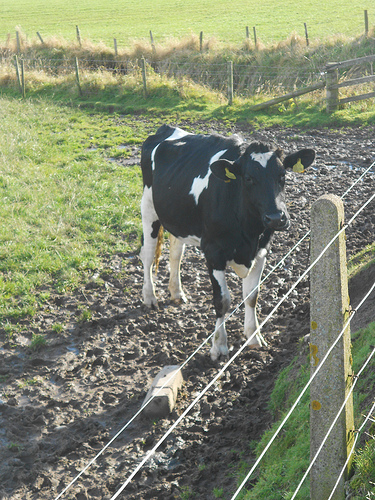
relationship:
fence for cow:
[1, 55, 375, 115] [136, 122, 316, 361]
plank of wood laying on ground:
[140, 365, 188, 420] [3, 2, 373, 500]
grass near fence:
[3, 4, 374, 335] [1, 55, 375, 115]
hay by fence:
[5, 40, 367, 71] [1, 55, 375, 115]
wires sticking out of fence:
[15, 55, 374, 88] [1, 55, 375, 115]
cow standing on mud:
[136, 122, 316, 361] [2, 111, 373, 498]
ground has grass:
[3, 2, 373, 500] [3, 4, 374, 335]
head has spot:
[234, 141, 291, 233] [249, 151, 277, 167]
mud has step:
[2, 111, 373, 498] [82, 345, 111, 363]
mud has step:
[2, 111, 373, 498] [142, 319, 159, 332]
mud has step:
[2, 111, 373, 498] [319, 165, 331, 178]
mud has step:
[2, 111, 373, 498] [290, 262, 300, 273]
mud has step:
[2, 111, 373, 498] [101, 294, 117, 307]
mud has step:
[2, 111, 373, 498] [203, 391, 222, 406]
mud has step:
[2, 111, 373, 498] [101, 392, 120, 405]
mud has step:
[2, 111, 373, 498] [177, 330, 190, 342]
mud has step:
[2, 111, 373, 498] [87, 434, 104, 450]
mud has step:
[2, 111, 373, 498] [55, 392, 71, 410]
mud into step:
[2, 111, 373, 498] [340, 159, 349, 169]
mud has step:
[2, 111, 373, 498] [78, 319, 92, 330]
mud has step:
[2, 111, 373, 498] [47, 364, 60, 378]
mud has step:
[2, 111, 373, 498] [132, 433, 170, 454]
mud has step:
[2, 111, 373, 498] [131, 271, 143, 284]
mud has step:
[2, 111, 373, 498] [295, 191, 306, 200]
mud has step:
[2, 111, 373, 498] [239, 352, 268, 365]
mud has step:
[2, 111, 373, 498] [41, 432, 62, 447]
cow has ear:
[136, 122, 316, 361] [211, 156, 241, 182]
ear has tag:
[211, 156, 241, 182] [222, 167, 242, 184]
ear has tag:
[282, 147, 316, 175] [292, 160, 308, 173]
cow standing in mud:
[136, 122, 316, 361] [2, 111, 373, 498]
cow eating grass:
[136, 122, 316, 361] [252, 225, 273, 252]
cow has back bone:
[136, 122, 316, 361] [155, 124, 244, 151]